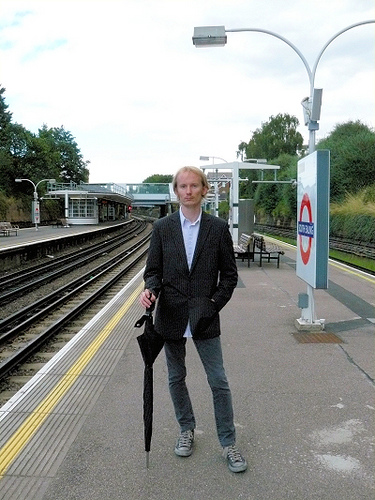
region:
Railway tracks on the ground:
[1, 208, 153, 375]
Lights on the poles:
[14, 19, 374, 331]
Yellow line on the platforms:
[1, 280, 144, 475]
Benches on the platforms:
[0, 218, 285, 265]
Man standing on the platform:
[140, 165, 247, 473]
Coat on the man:
[142, 210, 238, 341]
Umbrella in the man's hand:
[135, 291, 168, 469]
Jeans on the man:
[163, 336, 235, 447]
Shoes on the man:
[174, 431, 248, 474]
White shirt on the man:
[178, 205, 202, 336]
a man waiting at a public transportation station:
[1, 148, 329, 472]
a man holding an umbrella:
[133, 164, 248, 474]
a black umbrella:
[133, 288, 166, 469]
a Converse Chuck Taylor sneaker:
[219, 443, 247, 474]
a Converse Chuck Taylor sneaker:
[172, 427, 195, 458]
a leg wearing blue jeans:
[189, 334, 236, 447]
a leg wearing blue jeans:
[163, 336, 197, 432]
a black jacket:
[142, 208, 238, 339]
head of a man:
[171, 164, 210, 206]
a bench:
[251, 231, 285, 270]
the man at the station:
[139, 165, 245, 472]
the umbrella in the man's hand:
[133, 292, 164, 468]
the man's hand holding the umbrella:
[139, 289, 155, 308]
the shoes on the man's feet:
[174, 427, 247, 472]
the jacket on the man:
[143, 207, 237, 340]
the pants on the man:
[161, 334, 234, 448]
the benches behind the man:
[232, 233, 283, 267]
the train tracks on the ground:
[0, 214, 156, 408]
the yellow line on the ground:
[0, 278, 145, 479]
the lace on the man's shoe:
[221, 444, 242, 462]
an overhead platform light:
[190, 23, 225, 45]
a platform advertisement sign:
[293, 147, 325, 288]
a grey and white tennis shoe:
[221, 442, 244, 472]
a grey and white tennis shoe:
[173, 426, 190, 456]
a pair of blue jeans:
[164, 333, 236, 445]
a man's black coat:
[143, 206, 238, 339]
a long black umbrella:
[135, 303, 164, 465]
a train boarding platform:
[0, 222, 374, 496]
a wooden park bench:
[251, 231, 285, 264]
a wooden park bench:
[233, 231, 253, 261]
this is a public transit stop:
[45, 167, 309, 446]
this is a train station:
[20, 248, 278, 458]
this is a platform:
[23, 249, 186, 477]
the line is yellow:
[31, 384, 70, 447]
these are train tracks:
[6, 260, 109, 357]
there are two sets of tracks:
[25, 261, 89, 337]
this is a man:
[144, 172, 303, 467]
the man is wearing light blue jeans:
[149, 352, 250, 427]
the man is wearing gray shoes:
[164, 430, 261, 498]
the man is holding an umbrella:
[130, 289, 177, 461]